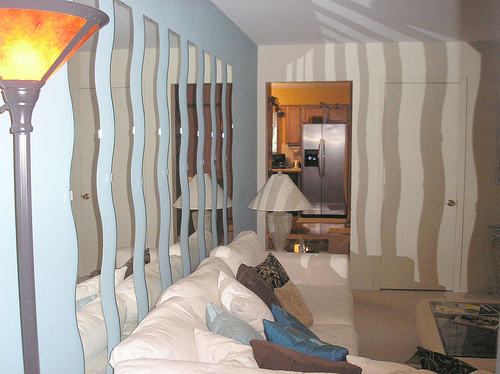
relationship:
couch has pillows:
[110, 230, 445, 374] [200, 250, 366, 372]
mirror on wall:
[160, 82, 234, 248] [3, 0, 255, 371]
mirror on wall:
[68, 0, 120, 371] [3, 0, 255, 371]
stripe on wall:
[268, 0, 500, 289] [289, 28, 494, 308]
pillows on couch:
[216, 235, 363, 368] [98, 225, 395, 372]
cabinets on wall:
[280, 104, 348, 142] [266, 84, 349, 218]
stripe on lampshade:
[268, 171, 285, 215] [240, 165, 314, 220]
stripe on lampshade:
[268, 0, 500, 289] [240, 165, 314, 220]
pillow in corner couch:
[193, 323, 260, 368] [103, 228, 438, 372]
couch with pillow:
[98, 225, 395, 372] [250, 248, 290, 287]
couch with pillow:
[98, 225, 395, 372] [234, 257, 281, 306]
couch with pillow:
[98, 225, 395, 372] [271, 275, 316, 330]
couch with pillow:
[98, 225, 395, 372] [214, 270, 276, 335]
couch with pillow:
[98, 225, 395, 372] [266, 313, 346, 358]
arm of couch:
[270, 252, 351, 282] [159, 190, 435, 372]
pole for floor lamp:
[2, 89, 37, 371] [1, 0, 111, 372]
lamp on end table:
[245, 170, 313, 254] [266, 232, 348, 253]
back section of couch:
[106, 231, 264, 361] [139, 294, 209, 351]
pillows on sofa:
[200, 250, 366, 372] [106, 221, 361, 369]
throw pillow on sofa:
[219, 272, 266, 322] [131, 233, 353, 371]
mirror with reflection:
[262, 81, 358, 253] [296, 120, 352, 219]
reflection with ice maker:
[172, 152, 238, 242] [305, 147, 318, 167]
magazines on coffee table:
[435, 298, 500, 332] [413, 298, 498, 373]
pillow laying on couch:
[405, 340, 477, 370] [107, 228, 487, 370]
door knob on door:
[443, 194, 455, 207] [356, 75, 464, 296]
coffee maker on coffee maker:
[272, 152, 285, 168] [272, 154, 286, 170]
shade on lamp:
[246, 170, 315, 216] [246, 167, 317, 254]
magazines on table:
[430, 295, 499, 332] [414, 294, 497, 372]